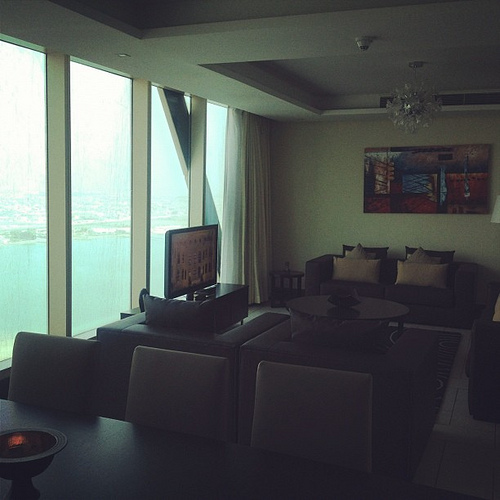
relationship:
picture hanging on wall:
[363, 145, 491, 216] [270, 119, 499, 290]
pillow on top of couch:
[337, 257, 377, 280] [306, 253, 477, 327]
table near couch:
[290, 294, 408, 329] [306, 253, 477, 327]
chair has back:
[251, 358, 370, 471] [251, 362, 370, 472]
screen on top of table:
[164, 225, 216, 297] [171, 282, 247, 329]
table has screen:
[171, 282, 247, 329] [164, 225, 216, 297]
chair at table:
[251, 358, 370, 471] [0, 399, 499, 499]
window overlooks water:
[70, 61, 132, 336] [3, 236, 165, 357]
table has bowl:
[290, 294, 408, 329] [330, 290, 359, 306]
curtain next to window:
[221, 106, 274, 302] [70, 61, 132, 336]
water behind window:
[3, 236, 165, 357] [70, 61, 132, 336]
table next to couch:
[271, 266, 304, 300] [306, 253, 477, 327]